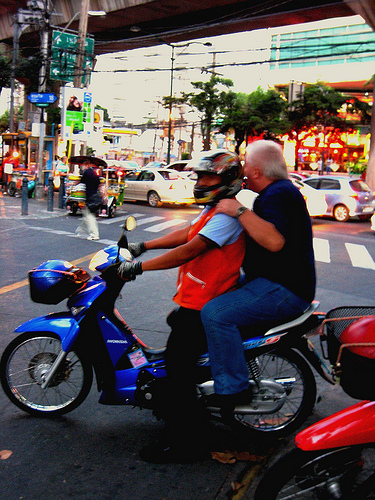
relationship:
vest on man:
[170, 208, 244, 310] [125, 146, 243, 469]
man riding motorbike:
[202, 139, 316, 415] [3, 215, 165, 415]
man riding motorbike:
[119, 150, 246, 463] [3, 215, 165, 415]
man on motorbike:
[119, 150, 246, 463] [1, 215, 373, 448]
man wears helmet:
[119, 150, 246, 463] [194, 151, 244, 204]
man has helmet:
[161, 150, 292, 343] [195, 152, 260, 205]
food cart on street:
[61, 153, 133, 221] [0, 191, 373, 496]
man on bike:
[202, 139, 316, 407] [0, 214, 329, 440]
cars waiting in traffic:
[117, 154, 197, 211] [50, 154, 372, 219]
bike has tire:
[10, 200, 368, 392] [2, 314, 90, 385]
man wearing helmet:
[119, 150, 246, 463] [188, 147, 245, 205]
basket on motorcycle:
[35, 248, 87, 305] [0, 216, 336, 439]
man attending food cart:
[80, 160, 103, 240] [63, 156, 123, 216]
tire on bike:
[1, 327, 97, 420] [0, 214, 329, 440]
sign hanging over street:
[50, 32, 86, 93] [0, 191, 373, 496]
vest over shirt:
[170, 208, 244, 310] [182, 200, 241, 250]